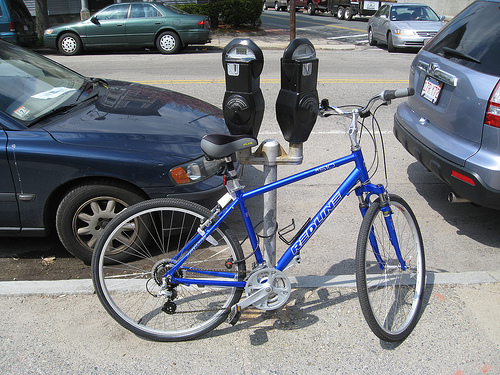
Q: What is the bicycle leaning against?
A: Parking meter.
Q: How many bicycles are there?
A: 1.